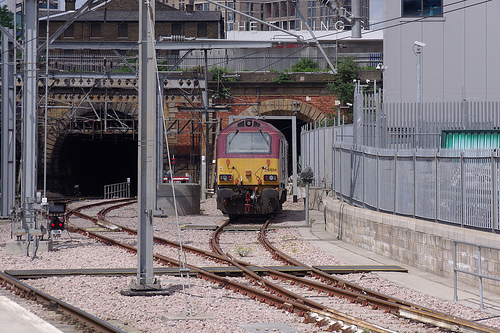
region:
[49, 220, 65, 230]
signal lights are red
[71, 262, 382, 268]
plank across the tracks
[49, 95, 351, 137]
arches in the wall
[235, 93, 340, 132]
the arch wall is brick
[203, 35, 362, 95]
bushes in front of building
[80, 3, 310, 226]
buildings behind the train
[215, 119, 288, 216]
Red and yellow train.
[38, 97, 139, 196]
Large brick arched entry way that is black inside.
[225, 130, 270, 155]
Dusty train windshield.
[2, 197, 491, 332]
All the brown tracks.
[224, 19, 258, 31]
White word THE up above the train.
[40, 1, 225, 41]
Darkest large brick brown building.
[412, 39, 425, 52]
A small white video camera.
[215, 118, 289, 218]
A single red and yellow train car.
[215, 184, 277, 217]
Black bottom metal plate of the train.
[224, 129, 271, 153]
Long train windshield.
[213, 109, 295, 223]
red and yellow train front on tracks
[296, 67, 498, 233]
silver metal fencing lining tracks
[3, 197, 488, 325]
brown gravel lining ground between tracks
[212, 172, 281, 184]
two unlit lights on front of train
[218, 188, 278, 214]
two black bumpers on front of train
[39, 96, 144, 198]
stone archway under bridge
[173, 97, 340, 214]
red brick archway under bridge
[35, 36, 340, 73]
silver metal railing on top of bridge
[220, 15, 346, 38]
silver letters free standing above bridge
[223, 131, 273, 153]
windoshield of front of train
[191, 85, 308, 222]
this is a train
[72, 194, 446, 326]
a set of train tracks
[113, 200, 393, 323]
the tracks split up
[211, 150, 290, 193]
yellow bottom half of train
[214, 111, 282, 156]
red top half on train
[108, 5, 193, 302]
rail next to tracks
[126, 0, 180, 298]
the rail is grey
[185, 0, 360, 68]
poles above the train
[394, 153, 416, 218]
This is a window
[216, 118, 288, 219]
the train is yellow and marroon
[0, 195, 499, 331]
the tracks are made of metal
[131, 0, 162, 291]
the pole is gray